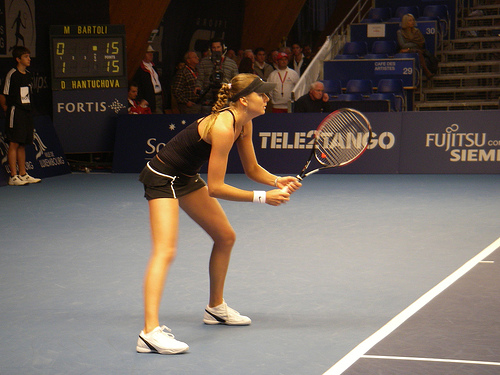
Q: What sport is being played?
A: Tennis.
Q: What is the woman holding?
A: A racket.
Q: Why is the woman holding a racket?
A: To hit the ball.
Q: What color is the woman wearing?
A: Black.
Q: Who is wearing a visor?
A: The tennis player.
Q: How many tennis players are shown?
A: One.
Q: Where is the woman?
A: On the court.